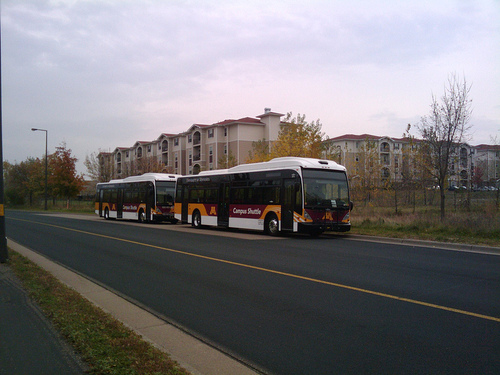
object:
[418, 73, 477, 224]
bare tree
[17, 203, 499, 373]
line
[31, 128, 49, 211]
street lamp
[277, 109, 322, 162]
tree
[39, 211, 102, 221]
sidewalk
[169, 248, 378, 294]
yellow paint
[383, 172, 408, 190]
ground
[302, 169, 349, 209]
windshield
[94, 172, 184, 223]
bus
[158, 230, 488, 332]
road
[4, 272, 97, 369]
ground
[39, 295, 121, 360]
ear tag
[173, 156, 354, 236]
bus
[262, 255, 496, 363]
stripe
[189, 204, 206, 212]
paint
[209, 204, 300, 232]
banner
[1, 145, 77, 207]
trees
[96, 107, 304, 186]
building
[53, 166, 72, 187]
leaves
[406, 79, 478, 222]
tree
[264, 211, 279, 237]
wheel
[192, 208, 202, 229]
wheel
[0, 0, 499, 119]
sky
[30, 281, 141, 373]
grass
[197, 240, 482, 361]
blacktop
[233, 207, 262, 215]
writing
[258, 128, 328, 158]
leaves